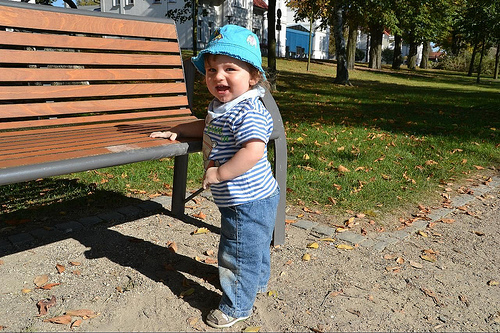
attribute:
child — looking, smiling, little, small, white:
[147, 20, 284, 331]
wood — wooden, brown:
[0, 1, 202, 168]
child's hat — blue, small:
[190, 22, 269, 81]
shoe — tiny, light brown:
[201, 307, 257, 329]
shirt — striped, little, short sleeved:
[200, 94, 280, 210]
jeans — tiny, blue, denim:
[214, 185, 283, 319]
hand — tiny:
[147, 126, 184, 142]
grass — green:
[1, 146, 207, 244]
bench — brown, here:
[2, 1, 289, 265]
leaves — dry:
[1, 76, 500, 327]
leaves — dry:
[2, 63, 498, 234]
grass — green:
[0, 34, 499, 250]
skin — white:
[148, 53, 281, 193]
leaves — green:
[169, 5, 499, 39]